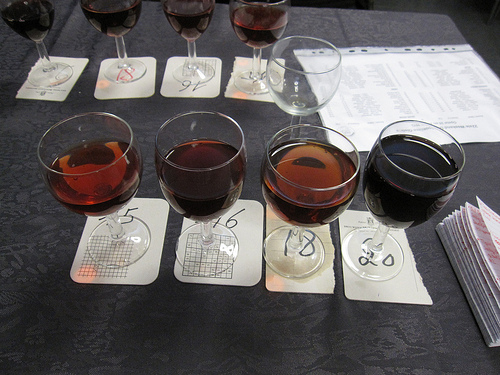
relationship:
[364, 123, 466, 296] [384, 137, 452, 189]
glass of wine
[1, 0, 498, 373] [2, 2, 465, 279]
table with glasses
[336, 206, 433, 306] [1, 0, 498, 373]
coaster on table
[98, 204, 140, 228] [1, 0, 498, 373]
15 on table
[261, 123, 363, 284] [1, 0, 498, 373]
glass on table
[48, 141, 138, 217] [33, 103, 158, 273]
wine in a glass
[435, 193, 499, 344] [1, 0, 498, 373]
notebook on table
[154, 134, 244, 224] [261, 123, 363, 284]
wine in glass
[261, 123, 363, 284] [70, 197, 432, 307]
glass on coasters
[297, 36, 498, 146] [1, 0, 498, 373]
paper on table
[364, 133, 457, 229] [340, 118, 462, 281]
liquid in glass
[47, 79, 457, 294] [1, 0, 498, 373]
glasses on table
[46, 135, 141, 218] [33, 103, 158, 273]
liquid in a glass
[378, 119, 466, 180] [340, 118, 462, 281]
rim of glass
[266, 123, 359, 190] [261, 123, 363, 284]
rim of glass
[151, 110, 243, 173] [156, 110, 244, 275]
rim of glass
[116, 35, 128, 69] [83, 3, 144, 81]
handle of glass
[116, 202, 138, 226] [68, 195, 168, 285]
number '5 on place holder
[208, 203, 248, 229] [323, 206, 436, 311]
number '16' on place holder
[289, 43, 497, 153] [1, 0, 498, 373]
paper on table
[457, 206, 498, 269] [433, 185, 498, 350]
notes in notebook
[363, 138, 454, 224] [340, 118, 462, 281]
red wine in glass